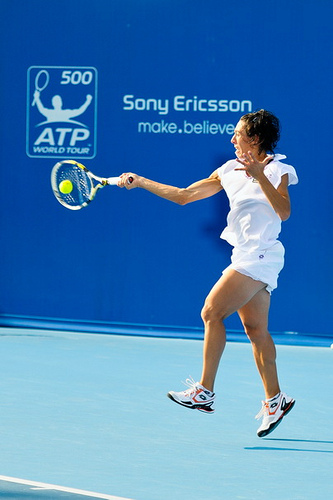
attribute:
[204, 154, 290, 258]
shirt — white, short sleeve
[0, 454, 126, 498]
line — white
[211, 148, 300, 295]
clothes — white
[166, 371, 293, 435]
shoes — white, black, red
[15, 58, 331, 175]
advertisement — white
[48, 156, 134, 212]
tennis racket — white, yellow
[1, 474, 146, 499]
white line — long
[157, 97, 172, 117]
letter — white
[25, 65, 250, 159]
writing — white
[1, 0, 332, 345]
wall — blue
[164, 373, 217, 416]
shoe — tennis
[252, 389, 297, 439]
shoe — tennis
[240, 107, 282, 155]
hair — black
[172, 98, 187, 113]
letter — white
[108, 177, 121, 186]
handle — white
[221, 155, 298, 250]
shirt — white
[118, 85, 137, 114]
letter — white